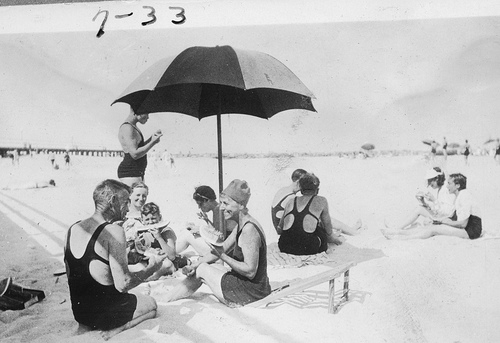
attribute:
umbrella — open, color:
[108, 37, 336, 132]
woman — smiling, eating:
[127, 180, 149, 226]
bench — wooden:
[277, 258, 376, 313]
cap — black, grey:
[224, 179, 263, 207]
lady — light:
[171, 179, 293, 307]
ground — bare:
[9, 154, 499, 338]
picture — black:
[3, 6, 477, 326]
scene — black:
[0, 6, 499, 335]